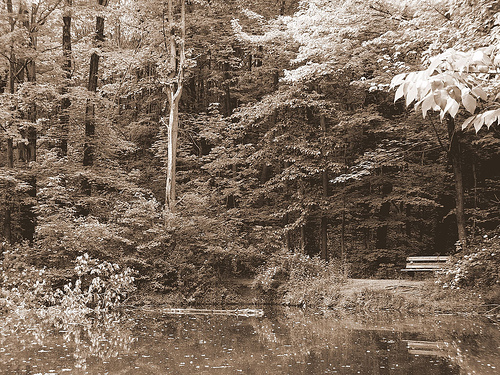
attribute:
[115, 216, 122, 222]
leaf — small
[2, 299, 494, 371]
pond — secluded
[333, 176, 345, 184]
leaf — small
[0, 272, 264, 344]
tree — fallen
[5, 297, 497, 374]
water — still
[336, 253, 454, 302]
cleared area — to enjoy the view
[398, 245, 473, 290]
bench — wood 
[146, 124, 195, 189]
trunk — forked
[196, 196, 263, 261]
leaf — small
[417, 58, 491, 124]
leaves — light, bent over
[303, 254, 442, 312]
area — open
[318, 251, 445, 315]
area — cleared